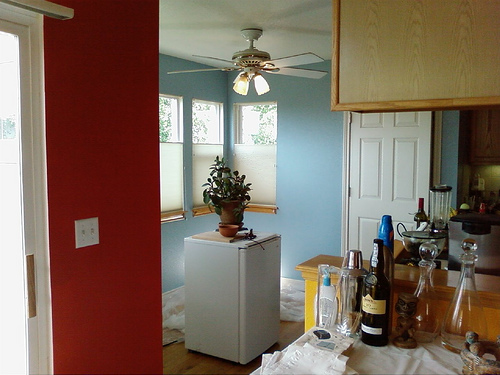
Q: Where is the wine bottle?
A: On the table.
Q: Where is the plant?
A: On top of the fridge.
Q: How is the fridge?
A: Small white colored mini fridge.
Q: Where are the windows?
A: At the far end.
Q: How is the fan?
A: A ceiling fan with six blades.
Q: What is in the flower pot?
A: The flower.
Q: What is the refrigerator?
A: Small dorm sized.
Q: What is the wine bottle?
A: Brown.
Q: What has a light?
A: The ceiling fan.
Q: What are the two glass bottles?
A: Clear.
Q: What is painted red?
A: The wall.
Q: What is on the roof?
A: The fan.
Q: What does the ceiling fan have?
A: The light.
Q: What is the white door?
A: Closed.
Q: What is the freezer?
A: Small and white.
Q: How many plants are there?
A: One.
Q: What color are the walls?
A: Red and blue.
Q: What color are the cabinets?
A: Brown.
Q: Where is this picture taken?
A: In a kitchen.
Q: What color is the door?
A: White.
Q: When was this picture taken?
A: In the daytime.